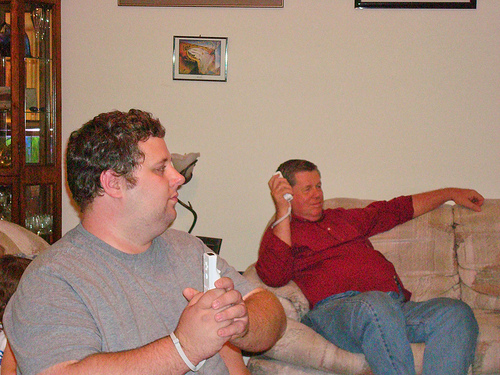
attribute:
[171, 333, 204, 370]
wrist band — white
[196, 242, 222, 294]
controller — video game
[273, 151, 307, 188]
hair — short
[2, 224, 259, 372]
shirt — gray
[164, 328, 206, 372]
bracelet — plastic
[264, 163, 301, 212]
controller — white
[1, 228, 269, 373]
t-shirt — gray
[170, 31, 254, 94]
art work — framed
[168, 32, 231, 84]
picture — framed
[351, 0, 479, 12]
black/wood frame — black, wood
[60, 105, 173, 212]
hair — brown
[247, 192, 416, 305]
shirt — red